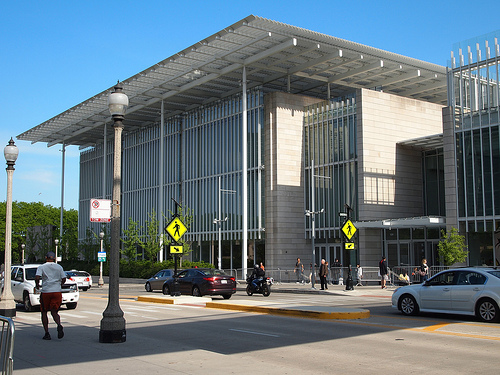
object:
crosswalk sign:
[166, 216, 188, 242]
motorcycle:
[246, 274, 273, 296]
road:
[0, 283, 500, 374]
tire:
[400, 294, 419, 315]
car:
[391, 267, 499, 323]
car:
[145, 269, 187, 292]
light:
[107, 91, 129, 116]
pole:
[99, 119, 126, 343]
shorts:
[40, 291, 63, 311]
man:
[35, 253, 67, 340]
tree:
[436, 227, 469, 269]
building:
[16, 13, 498, 285]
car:
[163, 268, 237, 299]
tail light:
[203, 277, 218, 281]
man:
[250, 265, 263, 291]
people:
[319, 259, 328, 290]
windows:
[424, 271, 456, 286]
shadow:
[3, 303, 462, 369]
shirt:
[36, 262, 66, 293]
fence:
[216, 267, 498, 285]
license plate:
[221, 280, 228, 284]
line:
[229, 329, 279, 338]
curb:
[206, 300, 370, 320]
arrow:
[348, 244, 352, 248]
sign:
[345, 242, 355, 249]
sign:
[89, 199, 111, 222]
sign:
[98, 252, 107, 262]